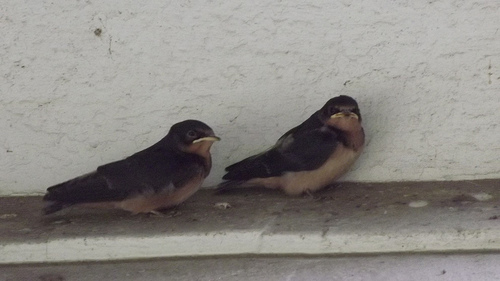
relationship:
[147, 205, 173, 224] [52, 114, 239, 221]
foot on bird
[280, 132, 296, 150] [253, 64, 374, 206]
feathers on bird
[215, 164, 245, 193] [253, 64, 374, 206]
feathers on bird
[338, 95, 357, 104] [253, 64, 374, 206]
feathers on bird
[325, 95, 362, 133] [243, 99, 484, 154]
head on bird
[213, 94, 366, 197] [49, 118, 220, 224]
bird next to bird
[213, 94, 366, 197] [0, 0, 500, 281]
bird on buillding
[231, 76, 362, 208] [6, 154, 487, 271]
bird on ledge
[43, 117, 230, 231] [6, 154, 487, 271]
bird on ledge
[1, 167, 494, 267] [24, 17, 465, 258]
ledge on buillding